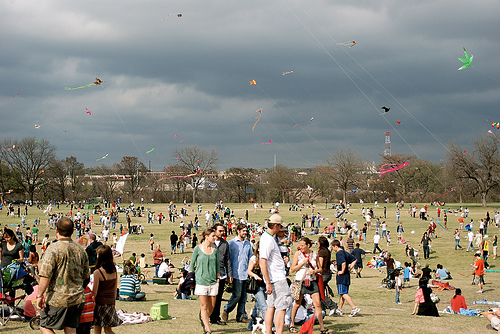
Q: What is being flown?
A: Kites.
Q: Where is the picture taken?
A: A park.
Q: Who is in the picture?
A: Men and women.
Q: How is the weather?
A: Overcast.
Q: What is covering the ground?
A: Grass.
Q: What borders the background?
A: Trees.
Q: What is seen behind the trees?
A: Buildings.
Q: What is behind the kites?
A: Trees and a town.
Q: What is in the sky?
A: Dark blue clouds.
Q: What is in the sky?
A: Colorful kites flying.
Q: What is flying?
A: Kite.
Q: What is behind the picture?
A: Trees.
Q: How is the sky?
A: Cloudy.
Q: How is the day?
A: Windy.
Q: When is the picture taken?
A: Daytime.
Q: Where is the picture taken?
A: At a kite festival.